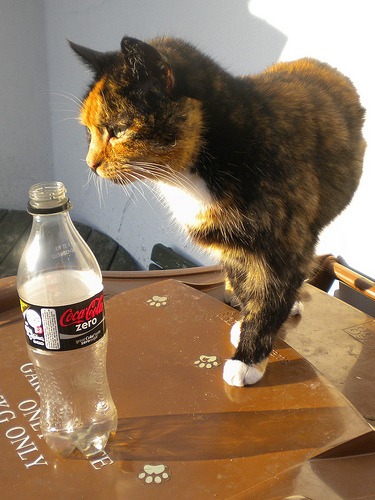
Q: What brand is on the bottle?
A: Coca-Cola.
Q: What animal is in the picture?
A: Cat.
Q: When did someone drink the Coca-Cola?
A: No indication of when.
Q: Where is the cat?
A: On top of trash bin.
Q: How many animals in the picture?
A: One.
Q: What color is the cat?
A: Brown, white and black.